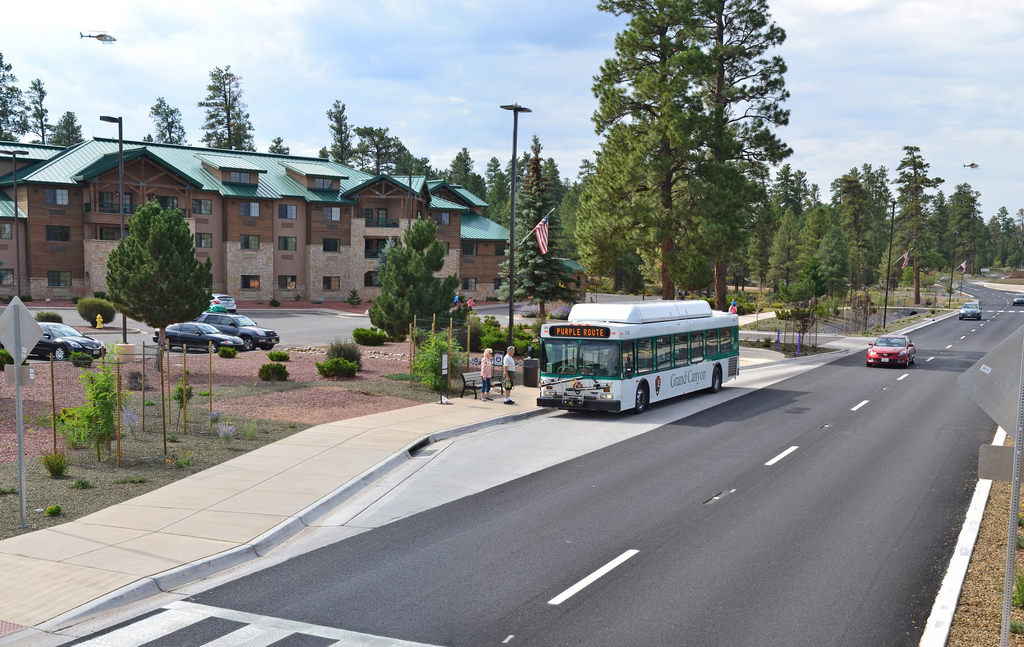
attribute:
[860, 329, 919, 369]
car — red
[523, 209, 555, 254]
flag — American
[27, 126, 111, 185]
roof — green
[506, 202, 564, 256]
flag — american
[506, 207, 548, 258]
flag — american